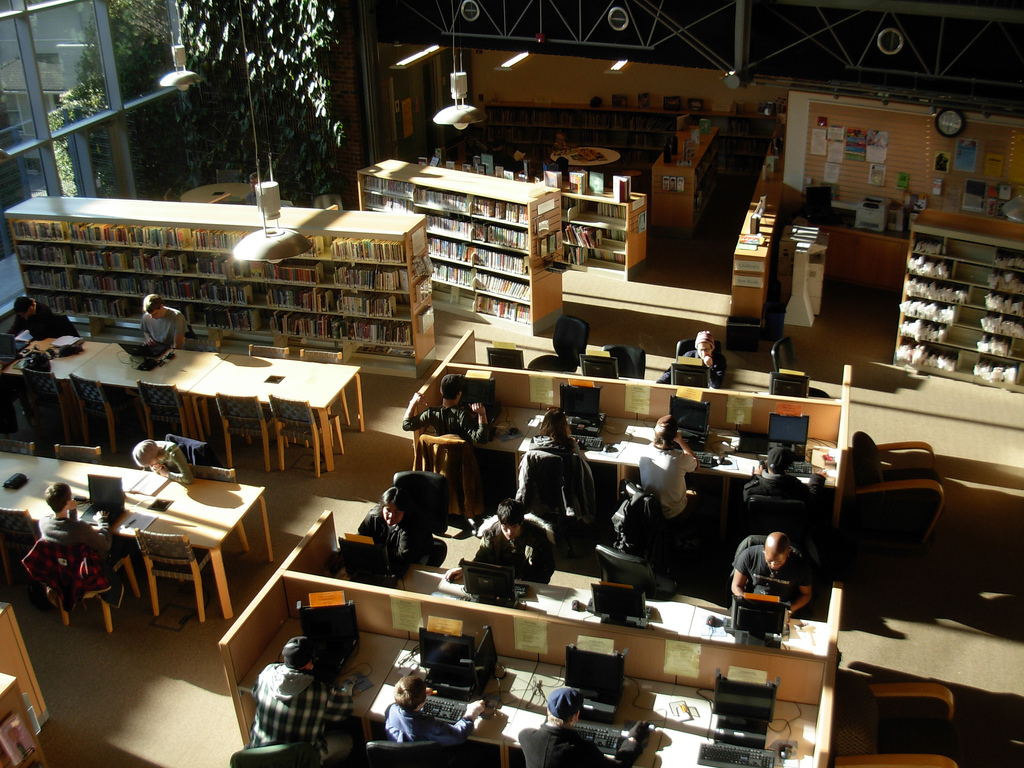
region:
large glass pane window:
[0, 0, 200, 315]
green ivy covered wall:
[167, 0, 352, 215]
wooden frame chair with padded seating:
[841, 432, 949, 546]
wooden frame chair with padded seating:
[828, 648, 964, 766]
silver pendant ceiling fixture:
[227, 0, 314, 269]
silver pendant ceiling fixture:
[429, 0, 490, 136]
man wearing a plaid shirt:
[246, 626, 358, 763]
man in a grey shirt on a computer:
[136, 294, 188, 349]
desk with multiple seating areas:
[217, 509, 843, 766]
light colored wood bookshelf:
[3, 195, 436, 374]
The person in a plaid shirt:
[233, 633, 355, 744]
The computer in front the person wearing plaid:
[282, 588, 374, 653]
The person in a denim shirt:
[378, 676, 470, 746]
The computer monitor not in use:
[469, 627, 518, 694]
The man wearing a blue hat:
[513, 684, 608, 764]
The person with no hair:
[720, 529, 815, 612]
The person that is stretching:
[396, 382, 488, 452]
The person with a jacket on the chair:
[511, 406, 587, 521]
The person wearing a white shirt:
[628, 409, 692, 524]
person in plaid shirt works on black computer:
[250, 592, 361, 755]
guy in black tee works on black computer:
[722, 533, 817, 644]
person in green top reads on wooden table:
[127, 434, 191, 486]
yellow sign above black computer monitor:
[305, 590, 347, 609]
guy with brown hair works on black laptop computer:
[38, 483, 114, 563]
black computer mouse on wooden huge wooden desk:
[705, 614, 718, 628]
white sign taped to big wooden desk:
[659, 637, 699, 677]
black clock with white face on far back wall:
[934, 107, 960, 137]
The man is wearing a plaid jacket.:
[253, 663, 336, 746]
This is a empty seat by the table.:
[132, 519, 219, 622]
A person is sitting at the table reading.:
[110, 423, 213, 490]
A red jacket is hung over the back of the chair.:
[10, 543, 119, 616]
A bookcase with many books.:
[21, 215, 415, 371]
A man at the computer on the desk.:
[707, 519, 812, 641]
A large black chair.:
[515, 303, 595, 383]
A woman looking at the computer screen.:
[667, 323, 722, 385]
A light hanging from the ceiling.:
[234, 158, 311, 275]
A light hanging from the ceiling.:
[416, 60, 494, 140]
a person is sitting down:
[242, 642, 359, 747]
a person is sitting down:
[352, 672, 466, 730]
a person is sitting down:
[520, 672, 603, 765]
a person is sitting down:
[485, 498, 542, 581]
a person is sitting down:
[368, 472, 420, 575]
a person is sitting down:
[522, 415, 581, 505]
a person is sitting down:
[629, 416, 688, 533]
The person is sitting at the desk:
[103, 382, 255, 519]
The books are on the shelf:
[333, 174, 587, 394]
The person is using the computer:
[250, 585, 371, 754]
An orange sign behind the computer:
[269, 569, 407, 678]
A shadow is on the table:
[4, 408, 270, 614]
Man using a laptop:
[40, 481, 133, 598]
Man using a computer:
[234, 634, 352, 764]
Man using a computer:
[377, 669, 479, 742]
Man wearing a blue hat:
[516, 674, 612, 766]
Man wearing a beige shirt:
[639, 414, 698, 517]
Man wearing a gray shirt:
[131, 293, 189, 351]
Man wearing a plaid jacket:
[245, 638, 362, 766]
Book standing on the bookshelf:
[604, 171, 637, 203]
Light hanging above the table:
[153, 0, 202, 99]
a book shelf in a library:
[357, 160, 560, 342]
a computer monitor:
[414, 628, 469, 674]